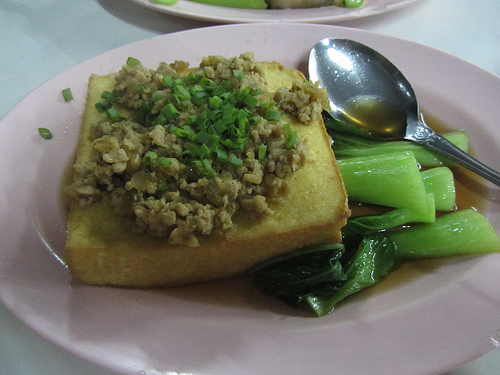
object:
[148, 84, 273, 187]
seasoning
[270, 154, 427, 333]
green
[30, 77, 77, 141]
chives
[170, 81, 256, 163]
green garnish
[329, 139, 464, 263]
green vegetables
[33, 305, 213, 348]
shadow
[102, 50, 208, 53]
two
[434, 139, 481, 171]
handle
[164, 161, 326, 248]
buttered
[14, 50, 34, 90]
tablecloth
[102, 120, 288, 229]
brown garnish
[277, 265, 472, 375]
bowl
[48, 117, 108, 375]
circular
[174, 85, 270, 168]
green onions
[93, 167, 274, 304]
top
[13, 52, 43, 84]
table top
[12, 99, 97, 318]
plates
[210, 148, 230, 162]
onion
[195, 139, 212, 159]
onion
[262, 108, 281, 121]
onion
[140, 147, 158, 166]
onion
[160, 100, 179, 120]
onion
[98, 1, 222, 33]
shadow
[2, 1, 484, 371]
table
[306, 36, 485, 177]
table spoon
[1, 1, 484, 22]
background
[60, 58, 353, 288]
bread piece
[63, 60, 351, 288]
sandwich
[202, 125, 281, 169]
chive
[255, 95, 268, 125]
chive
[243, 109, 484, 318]
side dish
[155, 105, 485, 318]
juice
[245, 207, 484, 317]
vegetable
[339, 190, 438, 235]
vegetable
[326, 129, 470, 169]
vegetable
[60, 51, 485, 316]
meal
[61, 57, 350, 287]
bread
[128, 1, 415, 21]
plate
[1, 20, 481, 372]
plate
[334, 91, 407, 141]
liquid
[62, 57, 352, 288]
bread slice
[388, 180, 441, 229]
food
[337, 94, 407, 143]
broth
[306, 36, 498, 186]
spoon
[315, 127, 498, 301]
broccoli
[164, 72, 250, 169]
chives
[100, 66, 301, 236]
tuna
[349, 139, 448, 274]
vegetables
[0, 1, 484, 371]
picture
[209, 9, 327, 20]
frame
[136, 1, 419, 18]
white plate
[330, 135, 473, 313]
chard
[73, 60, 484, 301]
food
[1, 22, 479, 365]
dish